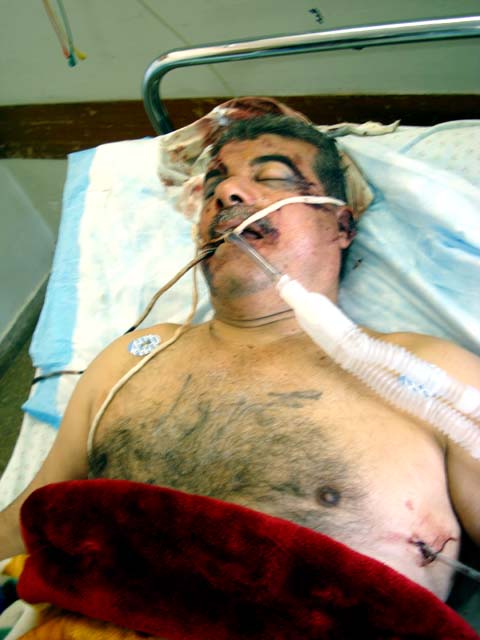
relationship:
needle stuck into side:
[418, 544, 466, 579] [352, 421, 461, 604]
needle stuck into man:
[418, 544, 466, 579] [0, 110, 464, 598]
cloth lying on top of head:
[152, 95, 401, 216] [194, 114, 359, 313]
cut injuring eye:
[294, 176, 316, 188] [253, 165, 293, 183]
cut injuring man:
[294, 176, 316, 188] [0, 110, 464, 598]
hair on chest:
[89, 366, 372, 555] [89, 374, 413, 505]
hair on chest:
[89, 366, 372, 555] [89, 400, 419, 516]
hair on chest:
[89, 366, 372, 555] [81, 389, 397, 513]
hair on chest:
[206, 477, 232, 496] [89, 400, 419, 516]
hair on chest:
[89, 366, 372, 555] [93, 416, 362, 500]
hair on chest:
[89, 366, 372, 555] [96, 448, 240, 534]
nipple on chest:
[306, 484, 351, 520] [152, 457, 417, 620]